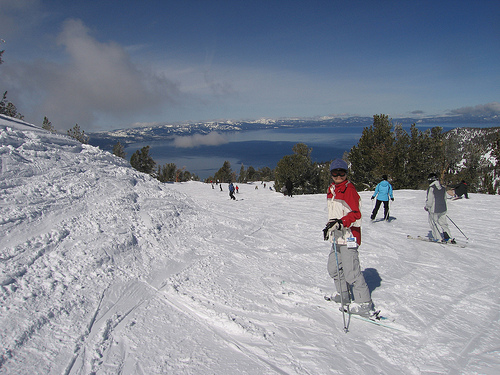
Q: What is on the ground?
A: Snow.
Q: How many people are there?
A: Three.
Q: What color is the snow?
A: White.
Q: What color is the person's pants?
A: Gray.